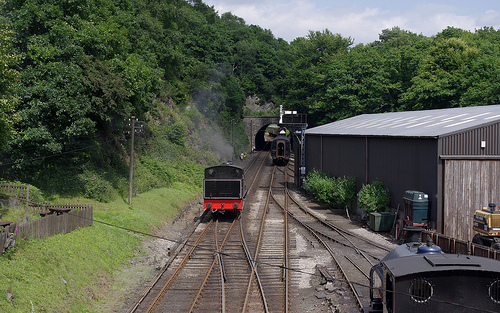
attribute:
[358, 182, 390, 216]
bush — green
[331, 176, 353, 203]
bush — green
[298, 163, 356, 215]
bush — green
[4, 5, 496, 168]
trees — green, tall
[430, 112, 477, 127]
stripes — yellow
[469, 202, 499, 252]
tractor — yellow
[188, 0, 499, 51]
sky — cloudy, blue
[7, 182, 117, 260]
fence — wood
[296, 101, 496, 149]
roof — grey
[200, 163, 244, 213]
train — red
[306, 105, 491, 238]
building — large, brown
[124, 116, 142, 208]
pole — wood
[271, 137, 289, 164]
train — heading for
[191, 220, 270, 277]
tracks — under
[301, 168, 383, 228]
bushes — green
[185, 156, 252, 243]
car — black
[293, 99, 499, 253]
building — metal, grey